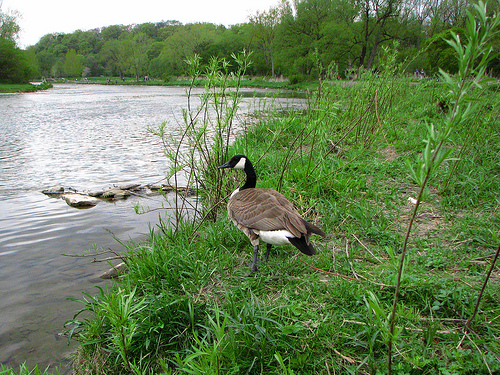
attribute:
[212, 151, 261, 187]
head — black, white 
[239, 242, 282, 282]
legs — Black 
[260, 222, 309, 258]
feathers — white 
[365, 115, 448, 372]
stick — Long , thin 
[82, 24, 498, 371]
grass — green 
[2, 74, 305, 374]
pond — small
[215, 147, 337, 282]
goose — white, brown, black 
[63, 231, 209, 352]
grass — green, brown, short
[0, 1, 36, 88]
green trees — green 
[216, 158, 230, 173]
bill — black 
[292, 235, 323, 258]
feathers — brown 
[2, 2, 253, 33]
sky — Gray 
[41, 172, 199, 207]
rocks — Flat 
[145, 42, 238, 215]
green plant — Green 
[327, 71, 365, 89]
land — Cleared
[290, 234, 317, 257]
feathers — Black 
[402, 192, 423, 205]
trash — White 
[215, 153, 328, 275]
duck — Black , white , brown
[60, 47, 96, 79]
tree — Big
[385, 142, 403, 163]
dirt — Thin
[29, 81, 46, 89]
canoe — White